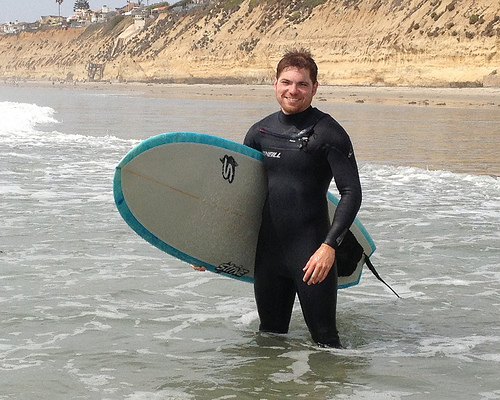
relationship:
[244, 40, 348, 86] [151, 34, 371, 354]
hair on man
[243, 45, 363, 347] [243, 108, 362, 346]
man wearing suit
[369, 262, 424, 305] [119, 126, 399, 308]
strap on surfboard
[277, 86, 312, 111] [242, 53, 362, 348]
beard on man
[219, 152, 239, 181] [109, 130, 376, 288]
sticker on a surfboard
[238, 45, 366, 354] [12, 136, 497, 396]
man standing in water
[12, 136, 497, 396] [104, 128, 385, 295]
water holding surfboard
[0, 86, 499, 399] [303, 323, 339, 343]
water up to mans knee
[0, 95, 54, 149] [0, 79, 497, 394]
foam on surface of water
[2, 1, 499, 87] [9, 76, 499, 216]
hillside along beach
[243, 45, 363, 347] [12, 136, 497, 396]
man in water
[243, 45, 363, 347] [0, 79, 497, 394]
man standing in water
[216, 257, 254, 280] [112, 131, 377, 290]
stine logo on a board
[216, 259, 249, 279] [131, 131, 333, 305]
stine on surfboard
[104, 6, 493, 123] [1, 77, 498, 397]
mountains near ocean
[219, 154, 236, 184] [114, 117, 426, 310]
sticker on surfboard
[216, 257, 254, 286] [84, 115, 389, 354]
letters on board